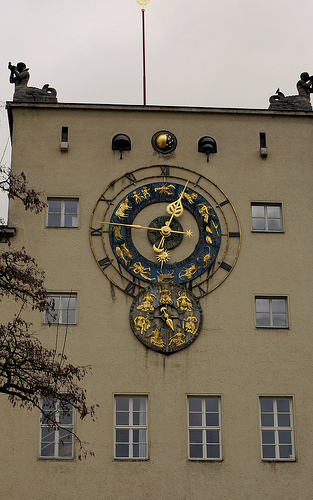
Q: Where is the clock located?
A: On the side of the building.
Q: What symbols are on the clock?
A: Zodiac signs.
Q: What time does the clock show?
A: 6:04.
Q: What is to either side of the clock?
A: Windows.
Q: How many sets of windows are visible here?
A: Eight.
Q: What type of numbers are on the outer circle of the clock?
A: Roman numerals.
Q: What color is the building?
A: Tan.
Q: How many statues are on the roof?
A: Two.